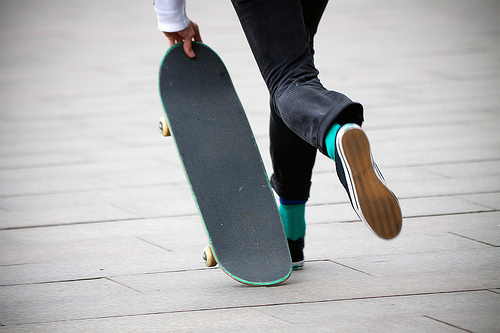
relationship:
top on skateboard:
[159, 34, 290, 282] [148, 37, 324, 293]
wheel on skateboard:
[200, 244, 217, 270] [153, 36, 296, 287]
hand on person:
[161, 18, 209, 61] [197, 0, 439, 288]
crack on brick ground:
[5, 265, 145, 286] [12, 217, 497, 329]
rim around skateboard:
[159, 38, 291, 286] [153, 36, 296, 287]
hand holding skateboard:
[162, 13, 204, 59] [153, 36, 296, 287]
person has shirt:
[154, 1, 404, 268] [153, 2, 189, 31]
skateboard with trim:
[153, 36, 296, 287] [157, 33, 292, 292]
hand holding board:
[158, 13, 209, 55] [155, 39, 292, 289]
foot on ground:
[329, 120, 406, 247] [11, 15, 152, 327]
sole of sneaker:
[341, 130, 402, 240] [334, 122, 405, 241]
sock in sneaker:
[279, 199, 305, 241] [287, 238, 304, 269]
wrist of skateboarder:
[155, 1, 186, 26] [153, 2, 405, 268]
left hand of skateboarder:
[162, 16, 204, 59] [153, 2, 405, 268]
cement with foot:
[108, 260, 188, 331] [271, 196, 327, 278]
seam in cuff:
[178, 4, 190, 27] [152, 0, 190, 33]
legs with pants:
[223, 2, 383, 255] [222, 2, 364, 171]